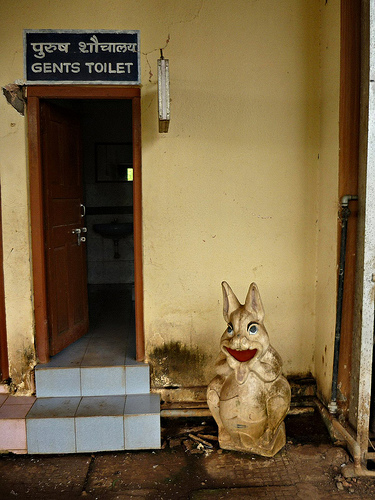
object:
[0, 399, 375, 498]
floor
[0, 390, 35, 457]
step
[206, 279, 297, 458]
figurine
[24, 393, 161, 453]
step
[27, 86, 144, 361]
door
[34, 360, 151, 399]
step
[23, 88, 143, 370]
doorway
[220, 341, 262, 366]
mouth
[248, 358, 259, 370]
hands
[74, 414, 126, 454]
tiles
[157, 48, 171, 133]
light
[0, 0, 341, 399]
wall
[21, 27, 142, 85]
black sign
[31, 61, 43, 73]
white letters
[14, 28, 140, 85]
white trim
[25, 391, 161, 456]
stairs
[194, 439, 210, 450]
trash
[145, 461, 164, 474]
trash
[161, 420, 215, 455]
trash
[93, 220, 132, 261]
sink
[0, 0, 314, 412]
bathroom